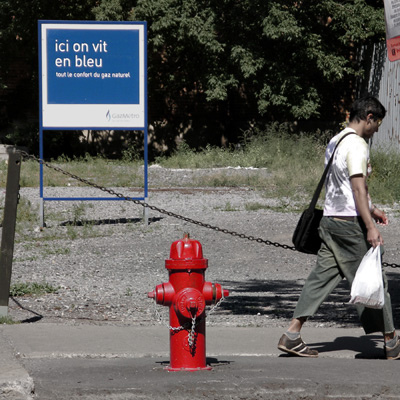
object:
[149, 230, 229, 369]
fire hydrant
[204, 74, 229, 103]
leaves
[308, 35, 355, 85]
tree branches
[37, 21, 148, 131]
sign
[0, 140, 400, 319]
fence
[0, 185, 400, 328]
driveway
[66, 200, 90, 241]
weeds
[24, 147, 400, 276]
chain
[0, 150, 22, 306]
post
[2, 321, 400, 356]
sidewalk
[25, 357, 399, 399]
street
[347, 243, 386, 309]
grocery bag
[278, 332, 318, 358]
sneaker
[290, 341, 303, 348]
stripes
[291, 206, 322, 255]
bag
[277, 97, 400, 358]
man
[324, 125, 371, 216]
shirt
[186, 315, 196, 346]
chain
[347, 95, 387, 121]
hair